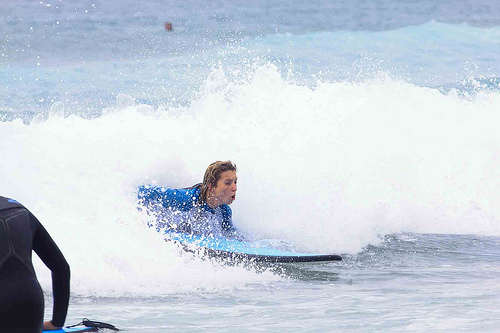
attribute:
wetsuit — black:
[1, 192, 103, 331]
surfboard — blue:
[153, 223, 352, 268]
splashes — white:
[198, 34, 288, 85]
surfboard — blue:
[166, 231, 343, 266]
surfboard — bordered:
[171, 227, 356, 270]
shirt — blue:
[138, 183, 233, 235]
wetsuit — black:
[3, 194, 70, 331]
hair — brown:
[190, 161, 235, 203]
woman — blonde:
[155, 157, 286, 244]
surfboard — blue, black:
[157, 219, 322, 266]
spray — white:
[242, 58, 499, 201]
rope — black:
[67, 311, 111, 328]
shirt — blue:
[131, 174, 206, 221]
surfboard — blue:
[165, 226, 343, 268]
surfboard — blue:
[180, 217, 379, 292]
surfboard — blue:
[153, 225, 364, 285]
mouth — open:
[222, 190, 237, 203]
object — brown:
[149, 12, 179, 36]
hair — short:
[195, 157, 238, 206]